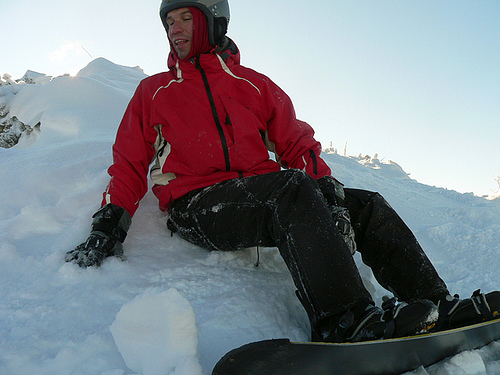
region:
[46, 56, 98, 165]
mountain of white snow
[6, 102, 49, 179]
snow covered rocks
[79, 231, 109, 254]
small label on black glove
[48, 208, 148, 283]
long black glove on hand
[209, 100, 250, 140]
black mark on red jacket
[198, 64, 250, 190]
long black zipper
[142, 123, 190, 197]
small cut on red jacket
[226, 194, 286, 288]
small black string on jacket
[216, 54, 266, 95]
white line in red jacket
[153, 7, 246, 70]
man wearing red scarf on head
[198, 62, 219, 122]
black zipper on a red coat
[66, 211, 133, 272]
a snow covered glove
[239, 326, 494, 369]
a black snowboard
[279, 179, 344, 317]
a leg of a black snowpant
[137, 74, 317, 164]
a red and white winter coat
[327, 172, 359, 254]
a black glove covered in snow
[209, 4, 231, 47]
a black safety helmet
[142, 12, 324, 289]
a guy sitting in the snow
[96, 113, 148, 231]
an arm of a person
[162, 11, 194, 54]
the face of a person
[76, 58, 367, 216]
The man is wearing a red jacket.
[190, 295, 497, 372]
The man has a snowboard attached to his feet.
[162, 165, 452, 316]
The man is wearing black pants.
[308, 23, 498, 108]
The sky is light blue.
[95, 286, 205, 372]
A big clump of snow.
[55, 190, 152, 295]
The man is wearing a glove.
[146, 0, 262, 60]
The man has a helmet on his head.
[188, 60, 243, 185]
The jacket has a black zipper.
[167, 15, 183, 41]
The man has a nose.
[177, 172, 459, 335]
The man has two legs.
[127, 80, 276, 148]
red and white jacket worn by snow boarder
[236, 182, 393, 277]
black pants worn by snow boarder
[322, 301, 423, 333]
black boot worn by snow boarder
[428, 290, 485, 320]
black boot worn by snow boarder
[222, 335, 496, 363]
black snow board used by snow boarder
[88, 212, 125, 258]
black glove worn by snow boarder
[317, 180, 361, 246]
black glove worn by snow boarder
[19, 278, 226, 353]
white snow on mountain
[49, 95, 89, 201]
white snow on mountain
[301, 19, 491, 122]
white clouds against blue sky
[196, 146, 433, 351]
A black pair of pants.